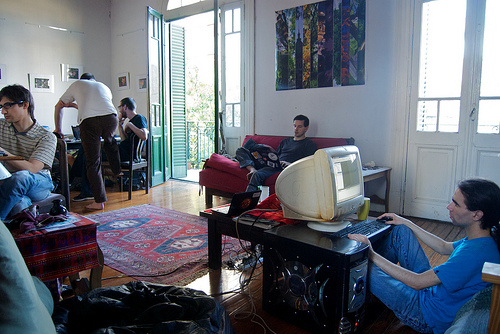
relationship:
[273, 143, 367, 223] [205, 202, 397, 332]
monitor sitting on table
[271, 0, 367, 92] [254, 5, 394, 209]
collage hanging on wall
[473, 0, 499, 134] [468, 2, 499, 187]
window on white door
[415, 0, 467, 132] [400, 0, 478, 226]
window on white door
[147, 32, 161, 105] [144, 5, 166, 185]
window on door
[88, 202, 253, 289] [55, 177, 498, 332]
rug on floor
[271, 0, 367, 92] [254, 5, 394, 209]
collage on wall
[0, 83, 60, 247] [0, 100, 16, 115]
man wearing glasses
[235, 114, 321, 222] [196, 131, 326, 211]
man sitting on couch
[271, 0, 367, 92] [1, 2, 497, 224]
collage hanging on wall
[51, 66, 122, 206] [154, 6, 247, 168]
man standing by door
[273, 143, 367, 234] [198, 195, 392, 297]
monitor on table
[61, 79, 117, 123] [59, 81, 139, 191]
white shirt on body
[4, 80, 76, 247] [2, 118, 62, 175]
man in shirt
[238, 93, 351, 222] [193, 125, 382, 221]
man on couch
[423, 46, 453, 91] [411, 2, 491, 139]
sunlight through windows